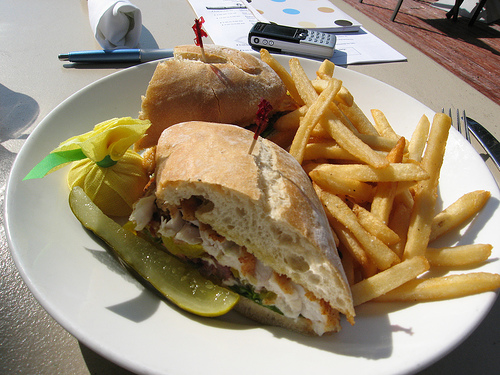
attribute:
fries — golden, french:
[308, 123, 478, 278]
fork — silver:
[438, 106, 468, 143]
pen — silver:
[53, 37, 145, 69]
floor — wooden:
[459, 49, 486, 96]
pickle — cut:
[55, 174, 245, 336]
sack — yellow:
[53, 112, 163, 222]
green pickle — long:
[68, 184, 241, 318]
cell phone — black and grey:
[250, 16, 337, 61]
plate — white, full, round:
[36, 59, 496, 371]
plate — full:
[7, 42, 484, 369]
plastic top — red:
[192, 11, 209, 50]